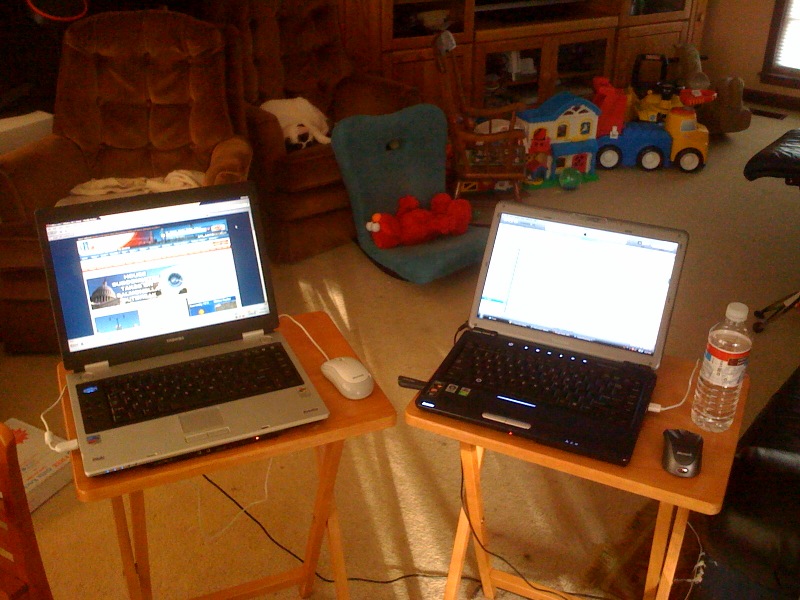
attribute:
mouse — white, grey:
[317, 352, 376, 400]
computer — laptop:
[413, 196, 689, 465]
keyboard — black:
[413, 328, 660, 467]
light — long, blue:
[496, 389, 538, 409]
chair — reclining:
[218, 2, 458, 259]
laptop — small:
[400, 186, 699, 476]